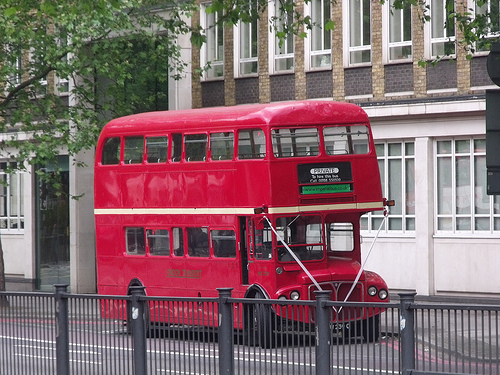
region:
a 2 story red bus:
[92, 100, 392, 340]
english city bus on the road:
[90, 98, 391, 336]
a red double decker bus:
[93, 98, 393, 343]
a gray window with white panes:
[433, 137, 498, 234]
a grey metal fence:
[0, 294, 495, 372]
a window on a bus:
[321, 118, 343, 165]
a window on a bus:
[351, 120, 376, 150]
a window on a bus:
[332, 219, 367, 272]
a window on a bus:
[279, 226, 314, 281]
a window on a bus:
[252, 218, 276, 255]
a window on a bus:
[207, 225, 245, 271]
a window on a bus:
[187, 214, 214, 252]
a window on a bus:
[125, 231, 143, 254]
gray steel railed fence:
[0, 294, 499, 374]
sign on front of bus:
[303, 165, 350, 195]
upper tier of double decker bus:
[96, 108, 380, 203]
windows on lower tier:
[125, 228, 240, 260]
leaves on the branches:
[5, 5, 139, 100]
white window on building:
[435, 136, 490, 231]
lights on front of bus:
[277, 289, 302, 310]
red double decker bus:
[93, 102, 415, 337]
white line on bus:
[100, 209, 242, 216]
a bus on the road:
[100, 88, 396, 373]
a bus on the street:
[136, 126, 321, 307]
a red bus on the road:
[132, 126, 369, 322]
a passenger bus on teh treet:
[97, 94, 384, 351]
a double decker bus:
[89, 105, 420, 350]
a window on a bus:
[271, 125, 321, 162]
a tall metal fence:
[89, 237, 275, 366]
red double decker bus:
[74, 65, 319, 347]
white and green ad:
[267, 147, 402, 217]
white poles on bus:
[258, 188, 389, 300]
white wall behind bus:
[378, 121, 483, 291]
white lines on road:
[130, 313, 247, 373]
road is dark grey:
[377, 288, 439, 369]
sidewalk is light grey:
[418, 301, 489, 373]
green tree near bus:
[8, 1, 159, 149]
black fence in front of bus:
[24, 273, 341, 374]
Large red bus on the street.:
[92, 99, 394, 348]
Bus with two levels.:
[91, 100, 389, 342]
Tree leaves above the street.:
[0, 0, 499, 200]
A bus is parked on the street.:
[0, 101, 392, 373]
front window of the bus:
[271, 128, 326, 156]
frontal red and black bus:
[266, 131, 380, 318]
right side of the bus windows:
[123, 233, 241, 248]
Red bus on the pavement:
[96, 126, 365, 293]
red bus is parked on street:
[90, 97, 393, 346]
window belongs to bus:
[98, 130, 121, 167]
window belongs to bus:
[122, 130, 144, 165]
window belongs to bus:
[183, 133, 206, 163]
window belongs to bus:
[234, 125, 265, 160]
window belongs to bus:
[122, 224, 144, 254]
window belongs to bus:
[147, 226, 171, 256]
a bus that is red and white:
[78, 116, 422, 367]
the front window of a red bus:
[252, 216, 369, 276]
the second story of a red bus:
[77, 86, 404, 257]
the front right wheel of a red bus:
[351, 312, 396, 344]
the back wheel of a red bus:
[107, 285, 167, 340]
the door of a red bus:
[225, 211, 269, 296]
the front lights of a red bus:
[274, 278, 388, 332]